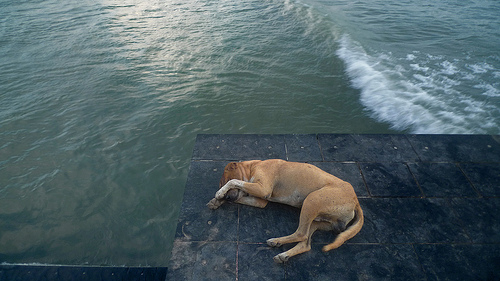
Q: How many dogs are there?
A: 1.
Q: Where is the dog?
A: Laying on the deck.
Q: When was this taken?
A: Daytime.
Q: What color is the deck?
A: Black.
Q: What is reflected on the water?
A: Sun.